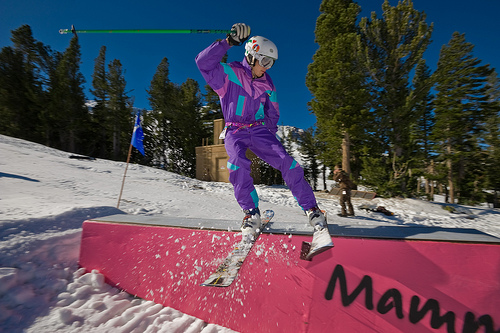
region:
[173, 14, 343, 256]
person in purple skiing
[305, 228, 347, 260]
ski on person's foot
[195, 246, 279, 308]
ski on person's foot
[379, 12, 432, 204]
ever green tree on side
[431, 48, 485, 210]
ever green tree on side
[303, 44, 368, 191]
ever green tree on side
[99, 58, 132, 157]
ever green tree on side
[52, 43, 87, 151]
ever green tree on side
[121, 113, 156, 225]
blue flag in ground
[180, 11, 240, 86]
This is a hand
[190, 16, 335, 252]
This is a person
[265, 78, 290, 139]
This is a hand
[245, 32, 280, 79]
Head of a person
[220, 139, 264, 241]
Leg of a person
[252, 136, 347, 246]
leg of a person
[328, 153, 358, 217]
This is a person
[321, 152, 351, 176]
Head of a person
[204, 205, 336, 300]
These are skating boards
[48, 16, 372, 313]
This is a man skating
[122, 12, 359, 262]
Person suspended in the air while skiiing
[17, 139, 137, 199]
Steep snowy slope with trees in the background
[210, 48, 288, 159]
Colorful skiing outfit with green and pink patches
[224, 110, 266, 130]
Bright colorful belt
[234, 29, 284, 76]
White and red skiing helmet and goggles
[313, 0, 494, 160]
Stand of tall green pine trees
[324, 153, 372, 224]
Skiier wearing brown clothing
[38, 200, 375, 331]
Pink colored jump for skiiers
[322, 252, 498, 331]
Black writing on a pink background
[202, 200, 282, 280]
Ski covered in snow attached to white shoe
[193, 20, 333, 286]
a roman flying over a ski ramp.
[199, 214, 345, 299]
a pair of snow covered skis.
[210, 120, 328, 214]
a pair of purple pants.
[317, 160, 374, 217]
a person standing in the snow.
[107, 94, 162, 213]
a flag on a ski slope.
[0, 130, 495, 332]
a snow covered ski slope.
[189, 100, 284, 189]
a brown multi story building.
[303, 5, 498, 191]
a forest of green trees.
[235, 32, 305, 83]
a white protective helmet.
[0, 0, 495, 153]
a clear blue sky.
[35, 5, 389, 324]
the man is jumping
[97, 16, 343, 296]
the man is skiing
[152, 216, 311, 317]
the snow is in the air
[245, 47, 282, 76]
the man is wearing goggles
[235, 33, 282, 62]
the man is wearing a helmet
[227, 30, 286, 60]
the helmet is white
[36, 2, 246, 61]
the man is holding a ski pole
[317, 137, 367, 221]
person standing in the background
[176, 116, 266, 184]
a tan building behind the man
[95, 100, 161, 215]
a flag in the snow